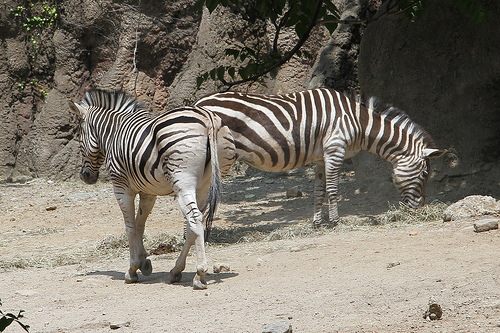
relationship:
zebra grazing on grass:
[183, 87, 449, 240] [373, 199, 451, 225]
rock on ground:
[472, 215, 500, 232] [0, 171, 499, 331]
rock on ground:
[440, 194, 500, 222] [0, 171, 499, 331]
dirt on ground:
[222, 252, 486, 331] [0, 171, 499, 331]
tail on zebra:
[206, 114, 221, 238] [66, 85, 226, 287]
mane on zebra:
[80, 87, 136, 112] [56, 77, 266, 314]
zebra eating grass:
[183, 87, 449, 240] [373, 199, 451, 225]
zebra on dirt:
[66, 88, 226, 291] [6, 167, 497, 331]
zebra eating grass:
[183, 87, 449, 240] [377, 198, 447, 227]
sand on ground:
[3, 178, 496, 331] [7, 136, 498, 331]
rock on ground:
[472, 213, 499, 232] [7, 136, 498, 331]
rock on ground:
[437, 195, 497, 218] [7, 136, 498, 331]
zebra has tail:
[66, 88, 226, 291] [181, 106, 239, 253]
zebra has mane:
[183, 87, 449, 240] [343, 88, 432, 148]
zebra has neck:
[183, 87, 449, 240] [348, 84, 408, 164]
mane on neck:
[343, 88, 432, 148] [348, 84, 408, 164]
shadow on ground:
[113, 259, 213, 279] [244, 246, 298, 273]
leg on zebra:
[114, 188, 153, 275] [66, 85, 226, 287]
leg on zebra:
[131, 192, 152, 278] [66, 85, 226, 287]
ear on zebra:
[415, 148, 450, 158] [242, 72, 459, 213]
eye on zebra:
[420, 166, 429, 178] [183, 87, 449, 240]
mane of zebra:
[343, 88, 432, 148] [183, 87, 449, 240]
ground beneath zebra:
[0, 171, 499, 331] [66, 85, 226, 287]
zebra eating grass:
[218, 90, 446, 219] [366, 200, 454, 230]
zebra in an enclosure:
[183, 87, 449, 240] [4, 2, 499, 332]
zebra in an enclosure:
[66, 85, 226, 287] [4, 2, 499, 332]